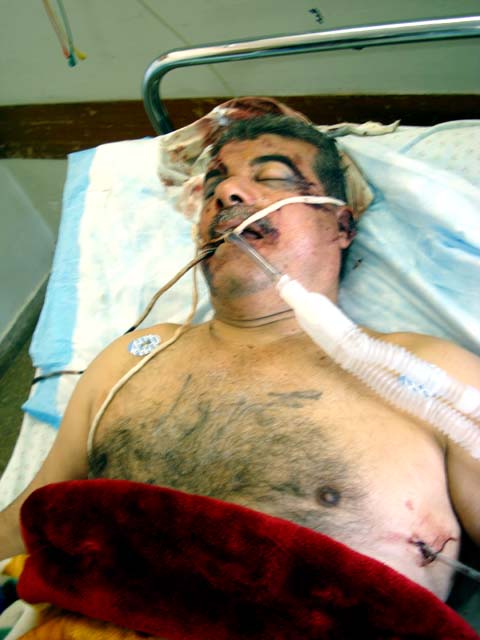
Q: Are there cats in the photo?
A: No, there are no cats.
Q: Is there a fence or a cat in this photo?
A: No, there are no cats or fences.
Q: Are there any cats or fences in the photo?
A: No, there are no cats or fences.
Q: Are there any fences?
A: No, there are no fences.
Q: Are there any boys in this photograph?
A: No, there are no boys.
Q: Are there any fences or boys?
A: No, there are no boys or fences.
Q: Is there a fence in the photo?
A: No, there are no fences.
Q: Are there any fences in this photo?
A: No, there are no fences.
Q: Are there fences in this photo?
A: No, there are no fences.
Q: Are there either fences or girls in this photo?
A: No, there are no fences or girls.